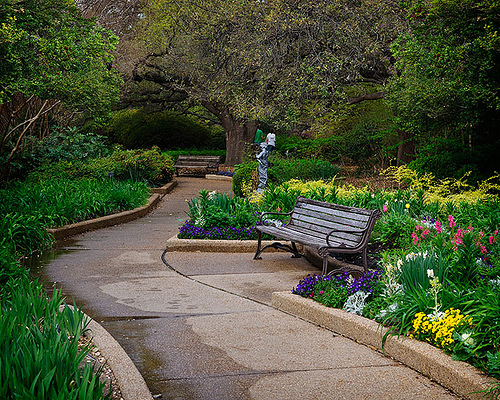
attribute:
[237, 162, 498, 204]
flowers — yellow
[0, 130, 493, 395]
grass — healthy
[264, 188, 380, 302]
bench — old, gray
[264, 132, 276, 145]
shirt — white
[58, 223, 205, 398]
ground — wet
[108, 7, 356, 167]
tree — big, yellow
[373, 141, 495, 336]
flowers — pink, beautiful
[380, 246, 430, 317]
flowers — white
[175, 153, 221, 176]
bench — distant